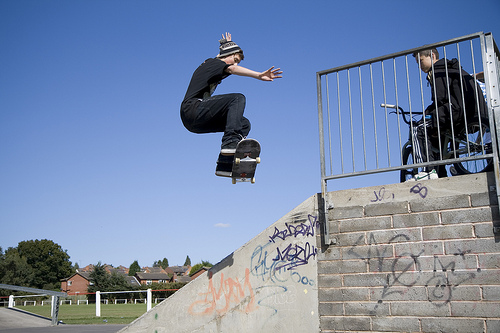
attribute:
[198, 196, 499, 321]
wall — brick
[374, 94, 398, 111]
handle — white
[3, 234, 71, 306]
tree — bushy, green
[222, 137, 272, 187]
skateboard — airborne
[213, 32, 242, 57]
beanie — black, white, knit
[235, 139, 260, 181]
skateboard — long, black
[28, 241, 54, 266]
leaves — green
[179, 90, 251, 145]
pants — jean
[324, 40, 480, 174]
poles — metal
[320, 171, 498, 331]
wall — brick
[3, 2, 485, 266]
sky — daytime